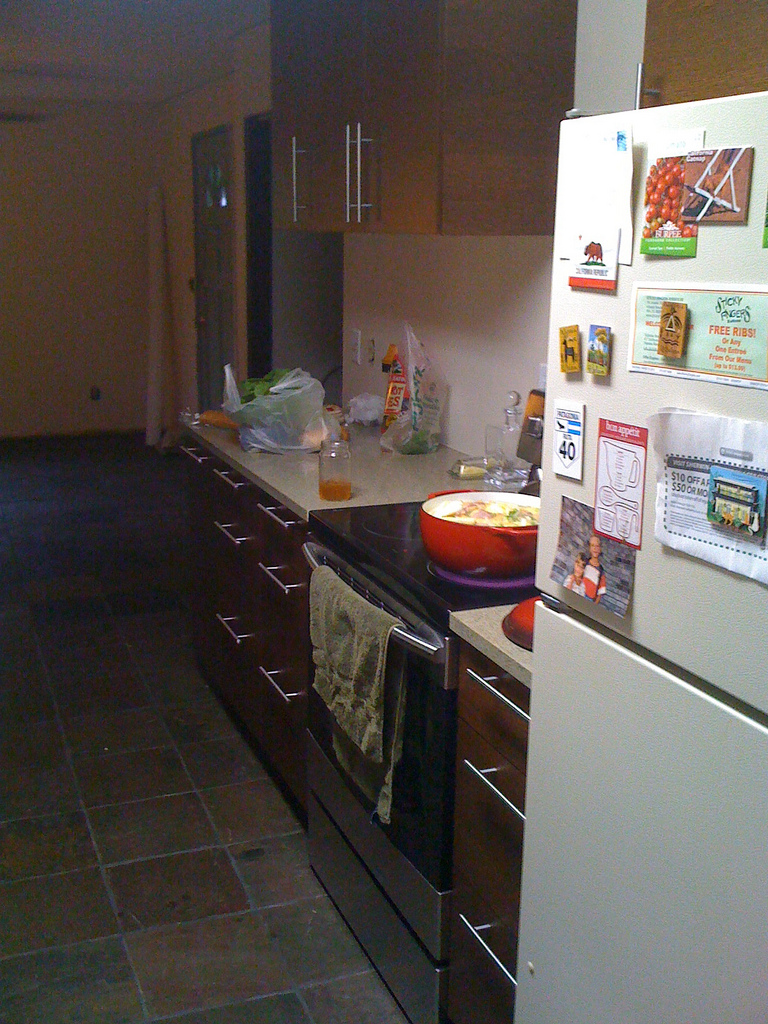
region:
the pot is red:
[421, 460, 560, 586]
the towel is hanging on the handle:
[242, 550, 434, 793]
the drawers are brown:
[446, 654, 550, 862]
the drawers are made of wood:
[442, 652, 548, 1003]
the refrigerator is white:
[517, 321, 766, 978]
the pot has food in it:
[438, 462, 547, 551]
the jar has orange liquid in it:
[281, 420, 381, 506]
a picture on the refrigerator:
[529, 470, 659, 631]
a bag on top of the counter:
[183, 335, 345, 454]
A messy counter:
[169, 354, 534, 525]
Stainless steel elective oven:
[296, 391, 546, 1014]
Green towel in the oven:
[302, 562, 412, 828]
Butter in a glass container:
[444, 451, 509, 485]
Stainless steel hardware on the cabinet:
[172, 437, 210, 467]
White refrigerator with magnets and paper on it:
[507, 84, 767, 1020]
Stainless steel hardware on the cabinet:
[210, 517, 257, 548]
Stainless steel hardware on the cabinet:
[252, 555, 304, 599]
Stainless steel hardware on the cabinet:
[288, 132, 309, 225]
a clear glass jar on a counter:
[314, 435, 356, 504]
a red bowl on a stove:
[411, 482, 537, 593]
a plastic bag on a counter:
[232, 362, 327, 458]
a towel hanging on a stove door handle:
[306, 543, 416, 826]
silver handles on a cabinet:
[336, 110, 370, 233]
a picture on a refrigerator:
[539, 499, 645, 625]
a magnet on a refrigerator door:
[657, 302, 689, 361]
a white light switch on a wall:
[342, 328, 367, 365]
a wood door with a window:
[181, 119, 242, 418]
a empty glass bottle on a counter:
[479, 401, 527, 487]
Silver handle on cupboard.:
[280, 135, 315, 231]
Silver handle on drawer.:
[460, 907, 515, 990]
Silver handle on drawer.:
[458, 747, 528, 829]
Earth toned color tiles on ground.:
[34, 742, 312, 1011]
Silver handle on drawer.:
[207, 601, 255, 660]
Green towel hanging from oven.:
[301, 564, 409, 818]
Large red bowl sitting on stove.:
[425, 486, 532, 579]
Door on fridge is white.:
[520, 630, 764, 1008]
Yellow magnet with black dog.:
[555, 329, 586, 380]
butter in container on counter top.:
[447, 456, 490, 482]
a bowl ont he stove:
[428, 444, 533, 570]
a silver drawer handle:
[462, 659, 570, 762]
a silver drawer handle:
[479, 749, 536, 837]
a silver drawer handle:
[475, 900, 512, 981]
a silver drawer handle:
[262, 561, 300, 596]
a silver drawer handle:
[264, 651, 302, 727]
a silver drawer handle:
[204, 596, 259, 651]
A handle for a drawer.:
[456, 907, 527, 992]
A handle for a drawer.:
[451, 752, 540, 823]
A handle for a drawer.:
[463, 652, 538, 721]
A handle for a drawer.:
[255, 659, 302, 706]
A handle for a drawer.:
[213, 606, 263, 645]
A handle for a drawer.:
[258, 555, 313, 603]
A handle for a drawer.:
[258, 498, 299, 530]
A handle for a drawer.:
[214, 506, 263, 553]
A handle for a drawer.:
[214, 467, 241, 493]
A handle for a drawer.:
[188, 442, 209, 466]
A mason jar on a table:
[317, 436, 353, 499]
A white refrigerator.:
[511, 92, 766, 1022]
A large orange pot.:
[414, 486, 539, 578]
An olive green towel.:
[299, 561, 412, 827]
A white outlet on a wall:
[347, 325, 362, 363]